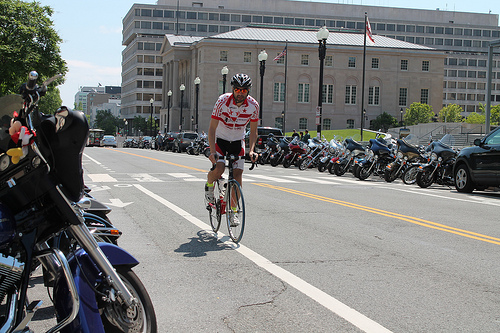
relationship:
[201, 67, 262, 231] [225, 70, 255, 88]
man with helmet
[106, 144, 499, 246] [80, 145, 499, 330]
yellow line in road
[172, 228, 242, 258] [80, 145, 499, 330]
shadow in road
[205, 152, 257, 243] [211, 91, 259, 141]
bicycle in jersey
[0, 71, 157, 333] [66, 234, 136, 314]
motorcycle has fender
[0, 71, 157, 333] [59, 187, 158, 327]
motorcycle has front fork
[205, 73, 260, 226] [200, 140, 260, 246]
man rides bicycle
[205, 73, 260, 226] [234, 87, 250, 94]
man wears glasses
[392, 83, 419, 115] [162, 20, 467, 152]
window on builiding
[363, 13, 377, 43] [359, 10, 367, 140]
flag on post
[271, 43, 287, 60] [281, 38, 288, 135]
flag on post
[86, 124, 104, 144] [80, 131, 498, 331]
bus on street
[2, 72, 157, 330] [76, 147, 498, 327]
motorcycle in street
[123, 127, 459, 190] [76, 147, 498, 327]
motorcycle in street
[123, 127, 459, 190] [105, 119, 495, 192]
motorcycle on row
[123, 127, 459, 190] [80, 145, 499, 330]
motorcycle on road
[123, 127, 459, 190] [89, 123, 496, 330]
motorcycle on road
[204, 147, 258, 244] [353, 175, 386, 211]
bicycle aside ground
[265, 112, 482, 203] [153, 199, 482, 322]
motorcycle on road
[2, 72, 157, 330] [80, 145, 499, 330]
motorcycle on road